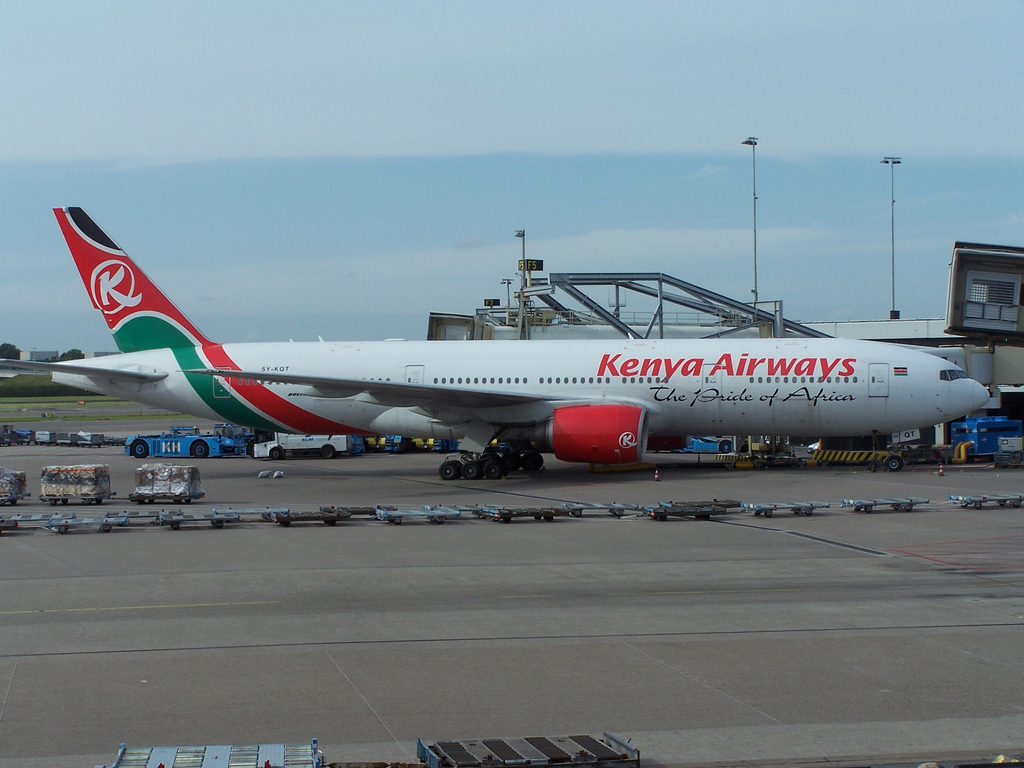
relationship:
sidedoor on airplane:
[351, 325, 445, 434] [55, 262, 982, 535]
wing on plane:
[25, 345, 160, 410] [4, 188, 996, 511]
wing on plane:
[172, 363, 657, 467] [6, 181, 1015, 452]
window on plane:
[435, 376, 479, 387] [4, 188, 996, 511]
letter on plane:
[659, 348, 683, 387] [9, 201, 988, 480]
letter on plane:
[759, 350, 794, 379] [9, 201, 988, 480]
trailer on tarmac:
[747, 487, 835, 520] [11, 389, 990, 742]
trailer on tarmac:
[747, 487, 835, 520] [11, 428, 971, 733]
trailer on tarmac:
[372, 497, 463, 532] [11, 428, 971, 733]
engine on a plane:
[528, 395, 663, 478] [9, 201, 988, 480]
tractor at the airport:
[121, 418, 243, 466] [7, 35, 993, 725]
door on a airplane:
[858, 355, 898, 401] [16, 195, 974, 485]